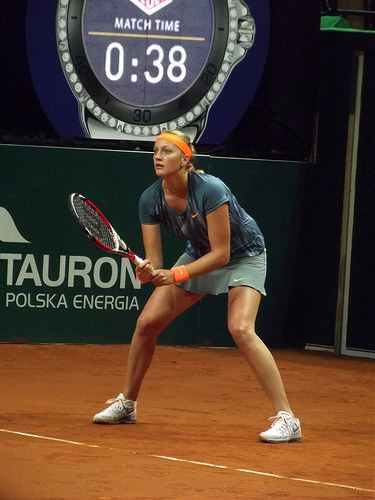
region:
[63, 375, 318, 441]
The woman is wearing white sneakers.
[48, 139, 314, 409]
Woman is playing tennis.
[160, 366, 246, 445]
Ground is brown color.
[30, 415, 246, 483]
White lines are in ground.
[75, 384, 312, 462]
Player is wearing white shoes.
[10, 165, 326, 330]
Barrier is green color.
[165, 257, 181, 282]
Player is wearing orange color band in wrist.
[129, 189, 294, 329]
Player is wearing grey color dress.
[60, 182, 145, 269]
Bat is red and white color.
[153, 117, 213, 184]
Player is wearing orange color hair band.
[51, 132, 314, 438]
Player is holding the tennis bat.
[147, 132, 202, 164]
a bright orange headband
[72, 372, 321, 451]
a pair of white tennis shoes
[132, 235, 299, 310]
a gray nike tennis skirt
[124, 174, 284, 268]
a gray nike athletic shirt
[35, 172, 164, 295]
a red and white tennis racket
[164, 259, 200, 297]
an orange nike wrist band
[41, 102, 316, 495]
a woman playing tennis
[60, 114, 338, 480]
a blond female athlete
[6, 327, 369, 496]
corner of a tennis court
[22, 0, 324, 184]
a large digital bilboard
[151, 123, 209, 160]
orange headband in woman's hair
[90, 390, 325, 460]
white sneakers without socks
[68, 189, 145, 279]
black and red tennis racket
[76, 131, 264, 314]
woman holding a tennis racket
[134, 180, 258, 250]
woman wearing a blue T-shirt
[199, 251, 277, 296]
woman wearing a gray skirt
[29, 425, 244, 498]
white line on a tennis court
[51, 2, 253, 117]
giant digital clock on the wall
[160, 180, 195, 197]
golden chain on woman's neck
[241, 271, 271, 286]
part of a skirt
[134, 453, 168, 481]
part of a ground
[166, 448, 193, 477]
part of a line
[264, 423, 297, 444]
part of a shoe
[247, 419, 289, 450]
edge of a shoe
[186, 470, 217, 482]
part of a ground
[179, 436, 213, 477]
part of a line